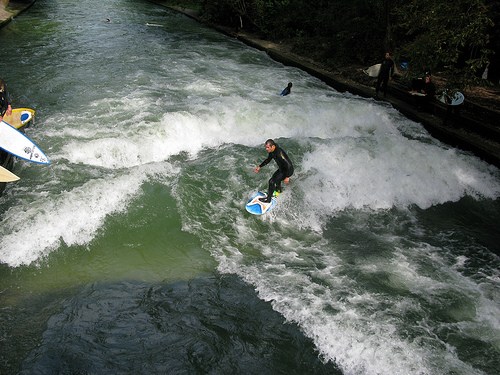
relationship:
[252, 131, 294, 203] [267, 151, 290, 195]
man wearing wetsuit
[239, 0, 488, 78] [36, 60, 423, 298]
trees near water